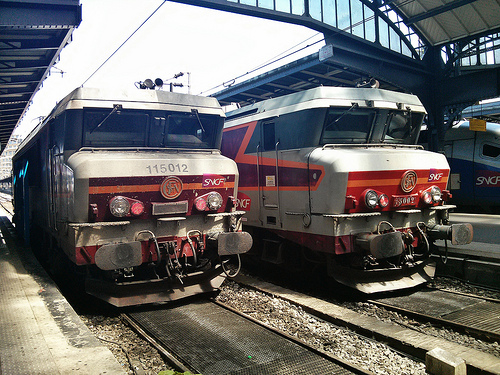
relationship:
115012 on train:
[142, 158, 192, 178] [11, 86, 254, 309]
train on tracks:
[11, 86, 254, 309] [162, 292, 494, 373]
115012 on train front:
[146, 163, 189, 174] [65, 87, 248, 305]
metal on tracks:
[237, 283, 292, 373] [160, 323, 314, 373]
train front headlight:
[67, 90, 277, 329] [363, 188, 380, 208]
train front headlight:
[274, 76, 492, 294] [349, 159, 497, 221]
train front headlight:
[11, 86, 254, 309] [110, 192, 130, 214]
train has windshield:
[218, 76, 474, 295] [318, 109, 427, 147]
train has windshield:
[11, 86, 254, 309] [79, 103, 221, 150]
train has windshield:
[11, 86, 254, 309] [67, 103, 229, 152]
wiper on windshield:
[191, 108, 206, 133] [67, 103, 229, 152]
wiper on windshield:
[90, 104, 121, 134] [67, 103, 229, 152]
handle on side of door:
[253, 138, 268, 221] [253, 116, 284, 231]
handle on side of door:
[271, 136, 288, 226] [253, 116, 284, 231]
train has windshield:
[11, 86, 254, 309] [82, 107, 220, 149]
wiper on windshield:
[92, 102, 121, 132] [82, 107, 220, 149]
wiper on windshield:
[191, 105, 206, 135] [82, 107, 220, 149]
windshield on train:
[313, 95, 432, 153] [217, 80, 476, 307]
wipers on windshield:
[321, 102, 360, 132] [313, 95, 432, 153]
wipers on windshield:
[400, 101, 415, 143] [313, 95, 432, 153]